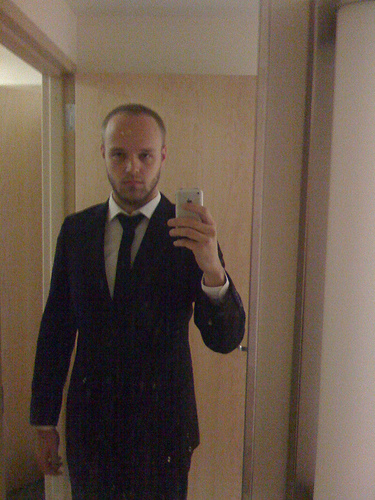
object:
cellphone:
[175, 188, 204, 241]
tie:
[113, 212, 145, 302]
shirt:
[104, 190, 162, 298]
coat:
[28, 188, 245, 473]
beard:
[106, 168, 162, 204]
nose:
[125, 153, 139, 176]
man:
[29, 102, 246, 499]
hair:
[100, 102, 167, 153]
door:
[74, 67, 258, 499]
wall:
[287, 5, 375, 495]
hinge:
[66, 104, 75, 129]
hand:
[168, 202, 223, 276]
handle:
[236, 344, 248, 352]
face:
[104, 112, 162, 202]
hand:
[33, 428, 63, 478]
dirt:
[118, 127, 132, 138]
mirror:
[1, 2, 374, 499]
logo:
[187, 198, 192, 203]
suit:
[29, 190, 246, 500]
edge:
[335, 0, 374, 14]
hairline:
[113, 113, 155, 118]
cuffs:
[198, 269, 232, 302]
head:
[101, 103, 167, 203]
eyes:
[139, 148, 153, 164]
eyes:
[111, 148, 126, 162]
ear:
[161, 145, 167, 166]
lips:
[123, 177, 145, 189]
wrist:
[204, 262, 225, 283]